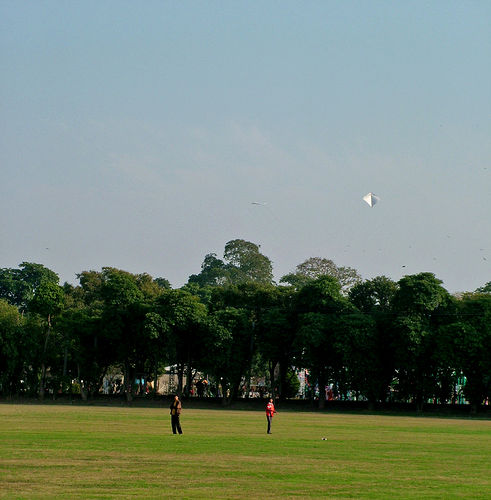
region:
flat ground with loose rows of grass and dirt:
[2, 399, 485, 494]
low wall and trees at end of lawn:
[0, 251, 485, 403]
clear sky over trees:
[0, 6, 484, 283]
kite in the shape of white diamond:
[353, 184, 375, 204]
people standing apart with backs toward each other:
[163, 382, 274, 435]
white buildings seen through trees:
[14, 359, 212, 392]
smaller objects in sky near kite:
[238, 158, 483, 267]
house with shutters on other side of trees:
[411, 364, 466, 400]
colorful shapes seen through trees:
[183, 373, 395, 398]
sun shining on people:
[162, 384, 280, 436]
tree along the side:
[187, 301, 232, 402]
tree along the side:
[290, 275, 332, 400]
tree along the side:
[329, 292, 380, 402]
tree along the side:
[393, 285, 446, 404]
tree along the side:
[80, 285, 142, 414]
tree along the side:
[23, 266, 66, 395]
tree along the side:
[1, 276, 50, 391]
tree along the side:
[55, 285, 107, 409]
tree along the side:
[428, 321, 475, 407]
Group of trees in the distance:
[3, 228, 489, 416]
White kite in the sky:
[350, 189, 385, 220]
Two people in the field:
[152, 386, 304, 458]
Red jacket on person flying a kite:
[259, 397, 280, 420]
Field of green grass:
[4, 386, 490, 497]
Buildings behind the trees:
[67, 343, 455, 417]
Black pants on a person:
[156, 405, 197, 440]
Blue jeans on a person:
[259, 409, 276, 435]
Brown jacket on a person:
[161, 393, 196, 416]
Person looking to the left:
[156, 390, 203, 431]